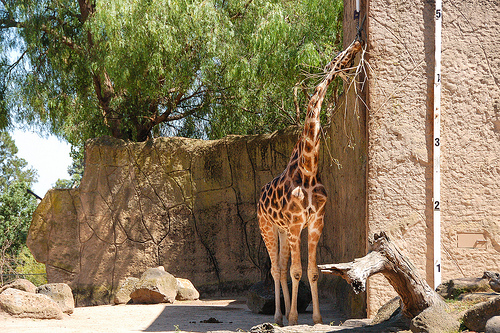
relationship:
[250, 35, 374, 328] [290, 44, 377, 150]
giraffe eating branch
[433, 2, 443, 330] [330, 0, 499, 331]
measuring stick on wall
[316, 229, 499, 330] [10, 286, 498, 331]
tree stump on ground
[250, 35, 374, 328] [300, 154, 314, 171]
giraffe has spot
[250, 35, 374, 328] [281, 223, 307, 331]
giraffe has leg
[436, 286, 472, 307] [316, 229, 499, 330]
moss growing on tree stump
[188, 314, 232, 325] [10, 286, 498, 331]
poop on ground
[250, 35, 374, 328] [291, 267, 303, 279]
giraffe has knee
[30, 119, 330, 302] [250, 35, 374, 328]
wall behind giraffe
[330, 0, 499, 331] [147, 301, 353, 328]
wall casting shadow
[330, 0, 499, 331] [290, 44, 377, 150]
wall has branch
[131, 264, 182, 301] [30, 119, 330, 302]
rock in front of wall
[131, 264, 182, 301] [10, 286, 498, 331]
rock sitting on ground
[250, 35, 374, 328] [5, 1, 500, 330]
giraffe in zoo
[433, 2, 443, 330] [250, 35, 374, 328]
measuring stick for measuring giraffe